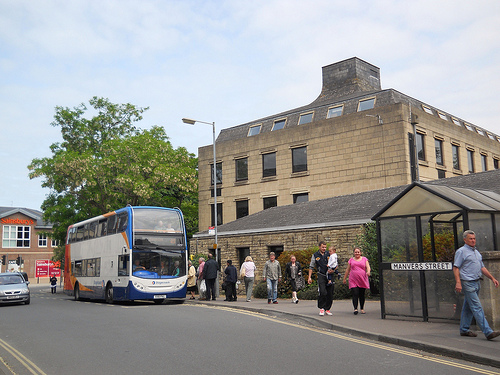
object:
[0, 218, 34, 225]
words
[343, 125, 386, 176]
bricks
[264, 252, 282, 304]
person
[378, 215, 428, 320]
glass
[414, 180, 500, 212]
roof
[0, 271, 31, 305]
car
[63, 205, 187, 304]
bus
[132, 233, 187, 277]
glass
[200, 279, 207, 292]
purse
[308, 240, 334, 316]
man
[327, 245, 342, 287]
baby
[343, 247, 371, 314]
woman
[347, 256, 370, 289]
dress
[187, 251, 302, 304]
people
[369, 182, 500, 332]
bus stop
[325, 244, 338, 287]
child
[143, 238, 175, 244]
sign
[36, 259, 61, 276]
sign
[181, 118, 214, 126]
street lamp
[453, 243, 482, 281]
shirt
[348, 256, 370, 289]
shirt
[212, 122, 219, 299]
pole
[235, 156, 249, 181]
window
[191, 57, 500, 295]
building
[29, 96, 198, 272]
tree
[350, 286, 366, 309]
pants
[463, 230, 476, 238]
hair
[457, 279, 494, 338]
jeans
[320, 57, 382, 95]
chimney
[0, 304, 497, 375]
road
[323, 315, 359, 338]
sidewalk